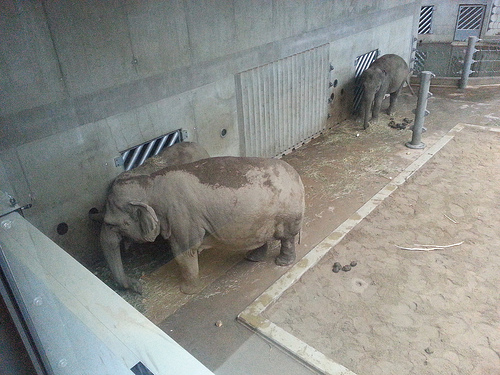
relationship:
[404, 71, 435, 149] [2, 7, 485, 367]
pole in a pen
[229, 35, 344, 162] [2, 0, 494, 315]
door in a wall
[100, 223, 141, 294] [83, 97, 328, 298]
trunk on an elephant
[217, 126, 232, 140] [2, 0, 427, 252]
hole in concrete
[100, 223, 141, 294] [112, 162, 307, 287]
trunk of an elephant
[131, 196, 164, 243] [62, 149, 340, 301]
ear of an elephant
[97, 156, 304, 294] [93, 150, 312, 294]
elephant of a elephant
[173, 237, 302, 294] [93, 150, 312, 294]
legs of a elephant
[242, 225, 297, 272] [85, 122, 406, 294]
legs of a elephant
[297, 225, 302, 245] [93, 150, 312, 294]
tail of a elephant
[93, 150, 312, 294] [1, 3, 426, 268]
elephant near a wall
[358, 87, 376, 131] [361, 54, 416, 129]
trunk of a elephant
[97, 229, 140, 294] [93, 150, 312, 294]
trunk of a elephant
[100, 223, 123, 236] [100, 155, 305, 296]
eye of a elephant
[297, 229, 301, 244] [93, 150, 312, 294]
tail of a elephant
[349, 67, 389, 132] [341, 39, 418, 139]
head of a elephant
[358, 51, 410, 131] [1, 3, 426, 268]
elephant near a wall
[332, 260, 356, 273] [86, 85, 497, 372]
dung on floor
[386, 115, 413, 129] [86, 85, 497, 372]
poop on floor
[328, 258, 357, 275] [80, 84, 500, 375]
dung on floor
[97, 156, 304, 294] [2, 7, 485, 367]
elephant in a pen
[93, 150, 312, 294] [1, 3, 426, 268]
elephant against wall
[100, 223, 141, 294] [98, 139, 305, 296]
trunk of elephant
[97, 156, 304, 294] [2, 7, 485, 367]
elephant in pen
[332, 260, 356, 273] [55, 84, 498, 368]
dung on ground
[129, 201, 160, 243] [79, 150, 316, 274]
ear on elephant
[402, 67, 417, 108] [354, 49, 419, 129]
tail on elephant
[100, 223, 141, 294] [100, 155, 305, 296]
trunk on elephant